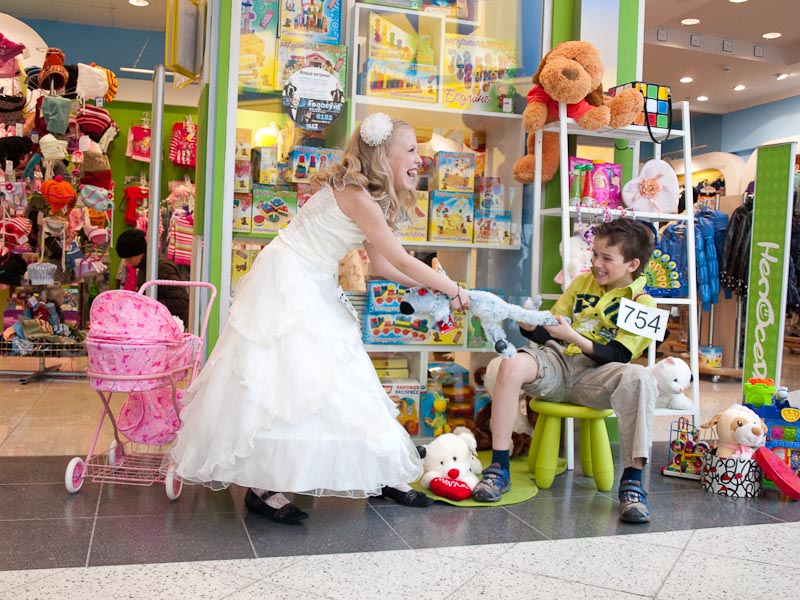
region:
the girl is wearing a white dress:
[155, 117, 471, 526]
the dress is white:
[157, 171, 426, 501]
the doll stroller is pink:
[62, 278, 216, 502]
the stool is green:
[525, 393, 614, 493]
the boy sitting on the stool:
[469, 216, 649, 525]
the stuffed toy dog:
[510, 41, 642, 179]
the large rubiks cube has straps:
[608, 81, 672, 151]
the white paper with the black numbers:
[616, 297, 668, 343]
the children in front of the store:
[1, 0, 795, 526]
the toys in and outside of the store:
[1, 1, 798, 508]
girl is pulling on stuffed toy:
[182, 123, 576, 525]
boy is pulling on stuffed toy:
[412, 213, 662, 536]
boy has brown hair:
[580, 218, 660, 295]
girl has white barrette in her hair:
[336, 105, 421, 220]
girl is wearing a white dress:
[178, 115, 470, 534]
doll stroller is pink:
[62, 276, 216, 498]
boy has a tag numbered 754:
[603, 292, 675, 344]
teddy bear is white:
[410, 426, 486, 504]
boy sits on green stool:
[470, 219, 667, 523]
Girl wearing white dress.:
[162, 90, 454, 524]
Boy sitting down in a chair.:
[475, 201, 672, 524]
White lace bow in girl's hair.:
[356, 107, 396, 150]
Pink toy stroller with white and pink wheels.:
[51, 270, 216, 505]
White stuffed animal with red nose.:
[420, 414, 496, 505]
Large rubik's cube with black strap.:
[609, 77, 679, 138]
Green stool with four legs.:
[521, 391, 620, 498]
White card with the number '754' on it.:
[613, 291, 665, 339]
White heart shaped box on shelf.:
[621, 153, 685, 218]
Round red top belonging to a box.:
[755, 446, 797, 506]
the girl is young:
[163, 120, 465, 521]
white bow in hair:
[361, 113, 393, 146]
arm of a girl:
[346, 195, 467, 311]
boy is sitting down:
[474, 219, 659, 525]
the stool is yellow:
[523, 396, 615, 494]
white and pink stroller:
[59, 277, 214, 501]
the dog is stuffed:
[514, 40, 637, 180]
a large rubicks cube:
[610, 79, 669, 130]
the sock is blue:
[490, 446, 511, 468]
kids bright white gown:
[201, 187, 428, 497]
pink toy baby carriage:
[61, 274, 201, 493]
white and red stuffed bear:
[415, 419, 485, 504]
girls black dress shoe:
[234, 488, 311, 530]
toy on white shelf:
[362, 61, 437, 99]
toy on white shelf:
[430, 187, 478, 237]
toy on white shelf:
[384, 185, 433, 247]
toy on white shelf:
[252, 177, 300, 237]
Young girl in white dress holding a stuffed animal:
[173, 109, 544, 529]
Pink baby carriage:
[58, 273, 212, 501]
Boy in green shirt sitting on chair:
[478, 209, 663, 524]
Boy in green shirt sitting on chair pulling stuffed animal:
[399, 217, 665, 525]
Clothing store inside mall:
[642, 2, 797, 440]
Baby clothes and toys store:
[2, 0, 646, 455]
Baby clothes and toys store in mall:
[4, 0, 648, 458]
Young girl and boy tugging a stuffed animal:
[160, 107, 659, 532]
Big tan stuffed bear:
[512, 41, 646, 182]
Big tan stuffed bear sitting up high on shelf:
[513, 41, 641, 193]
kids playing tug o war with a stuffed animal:
[179, 103, 675, 530]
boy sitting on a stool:
[481, 208, 676, 533]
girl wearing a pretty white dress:
[161, 100, 436, 522]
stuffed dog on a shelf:
[503, 28, 650, 188]